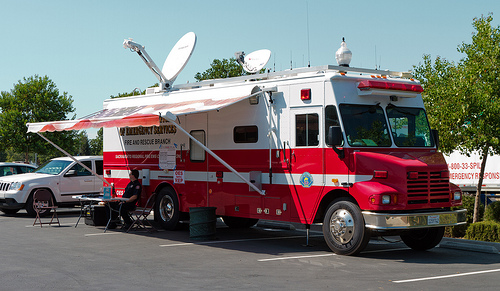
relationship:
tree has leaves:
[411, 11, 499, 225] [410, 13, 499, 148]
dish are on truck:
[120, 30, 199, 89] [23, 30, 467, 256]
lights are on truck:
[355, 80, 424, 93] [23, 30, 467, 256]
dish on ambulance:
[120, 31, 199, 92] [23, 30, 467, 256]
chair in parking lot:
[31, 187, 61, 227] [0, 208, 498, 289]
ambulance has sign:
[23, 30, 467, 256] [173, 169, 185, 184]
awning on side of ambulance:
[27, 88, 269, 198] [23, 30, 467, 256]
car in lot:
[0, 153, 102, 215] [0, 208, 498, 289]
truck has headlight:
[23, 30, 467, 256] [380, 193, 393, 206]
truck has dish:
[23, 30, 467, 256] [120, 30, 199, 89]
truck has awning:
[23, 30, 467, 256] [27, 88, 269, 198]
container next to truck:
[82, 203, 119, 227] [23, 30, 467, 256]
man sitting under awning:
[105, 167, 141, 232] [27, 88, 269, 198]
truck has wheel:
[23, 30, 467, 256] [397, 226, 444, 252]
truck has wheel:
[23, 30, 467, 256] [151, 183, 189, 231]